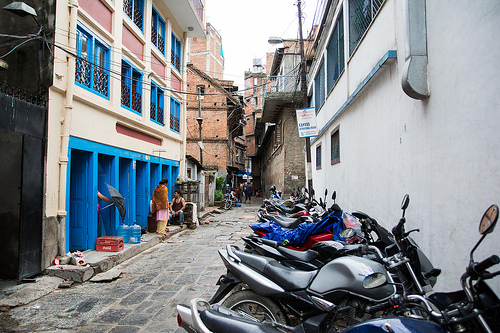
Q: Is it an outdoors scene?
A: Yes, it is outdoors.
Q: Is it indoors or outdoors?
A: It is outdoors.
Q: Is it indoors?
A: No, it is outdoors.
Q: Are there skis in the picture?
A: No, there are no skis.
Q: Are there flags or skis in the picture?
A: No, there are no skis or flags.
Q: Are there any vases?
A: No, there are no vases.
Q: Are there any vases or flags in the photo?
A: No, there are no vases or flags.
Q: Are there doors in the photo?
A: Yes, there is a door.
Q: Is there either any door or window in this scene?
A: Yes, there is a door.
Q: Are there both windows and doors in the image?
A: Yes, there are both a door and a window.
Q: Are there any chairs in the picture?
A: No, there are no chairs.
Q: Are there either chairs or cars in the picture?
A: No, there are no chairs or cars.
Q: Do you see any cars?
A: No, there are no cars.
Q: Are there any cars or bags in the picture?
A: No, there are no cars or bags.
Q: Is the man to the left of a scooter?
A: No, the man is to the left of a motorcycle.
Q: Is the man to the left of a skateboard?
A: No, the man is to the left of a motorcycle.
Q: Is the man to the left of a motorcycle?
A: Yes, the man is to the left of a motorcycle.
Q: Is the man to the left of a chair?
A: No, the man is to the left of a motorcycle.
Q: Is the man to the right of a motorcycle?
A: No, the man is to the left of a motorcycle.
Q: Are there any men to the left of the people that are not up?
A: Yes, there is a man to the left of the people.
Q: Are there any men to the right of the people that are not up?
A: No, the man is to the left of the people.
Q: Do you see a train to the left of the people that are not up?
A: No, there is a man to the left of the people.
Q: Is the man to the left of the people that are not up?
A: Yes, the man is to the left of the people.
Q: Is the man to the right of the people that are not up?
A: No, the man is to the left of the people.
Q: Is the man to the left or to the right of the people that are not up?
A: The man is to the left of the people.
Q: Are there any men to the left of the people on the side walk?
A: Yes, there is a man to the left of the people.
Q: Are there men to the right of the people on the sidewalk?
A: No, the man is to the left of the people.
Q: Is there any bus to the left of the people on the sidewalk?
A: No, there is a man to the left of the people.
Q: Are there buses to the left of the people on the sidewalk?
A: No, there is a man to the left of the people.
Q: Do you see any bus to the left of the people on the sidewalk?
A: No, there is a man to the left of the people.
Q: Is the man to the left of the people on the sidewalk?
A: Yes, the man is to the left of the people.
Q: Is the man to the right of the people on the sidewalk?
A: No, the man is to the left of the people.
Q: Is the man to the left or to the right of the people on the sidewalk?
A: The man is to the left of the people.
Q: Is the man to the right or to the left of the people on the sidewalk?
A: The man is to the left of the people.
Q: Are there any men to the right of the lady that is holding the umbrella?
A: Yes, there is a man to the right of the lady.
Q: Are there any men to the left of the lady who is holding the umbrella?
A: No, the man is to the right of the lady.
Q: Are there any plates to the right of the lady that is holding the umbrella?
A: No, there is a man to the right of the lady.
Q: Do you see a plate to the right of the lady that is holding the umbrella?
A: No, there is a man to the right of the lady.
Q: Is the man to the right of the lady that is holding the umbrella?
A: Yes, the man is to the right of the lady.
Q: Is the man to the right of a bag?
A: No, the man is to the right of the lady.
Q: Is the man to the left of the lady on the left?
A: No, the man is to the right of the lady.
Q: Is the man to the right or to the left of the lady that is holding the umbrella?
A: The man is to the right of the lady.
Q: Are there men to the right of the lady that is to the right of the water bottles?
A: Yes, there is a man to the right of the lady.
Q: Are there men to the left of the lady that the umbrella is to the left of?
A: No, the man is to the right of the lady.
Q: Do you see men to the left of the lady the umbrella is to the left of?
A: No, the man is to the right of the lady.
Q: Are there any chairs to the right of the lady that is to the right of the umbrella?
A: No, there is a man to the right of the lady.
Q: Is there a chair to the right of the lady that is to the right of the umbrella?
A: No, there is a man to the right of the lady.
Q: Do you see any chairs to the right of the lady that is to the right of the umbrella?
A: No, there is a man to the right of the lady.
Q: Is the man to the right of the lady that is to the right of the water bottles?
A: Yes, the man is to the right of the lady.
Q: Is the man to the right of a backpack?
A: No, the man is to the right of the lady.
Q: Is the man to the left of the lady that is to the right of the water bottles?
A: No, the man is to the right of the lady.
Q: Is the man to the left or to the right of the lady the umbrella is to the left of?
A: The man is to the right of the lady.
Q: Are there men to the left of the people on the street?
A: Yes, there is a man to the left of the people.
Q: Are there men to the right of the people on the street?
A: No, the man is to the left of the people.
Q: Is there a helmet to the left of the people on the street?
A: No, there is a man to the left of the people.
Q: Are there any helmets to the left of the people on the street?
A: No, there is a man to the left of the people.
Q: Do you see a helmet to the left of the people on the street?
A: No, there is a man to the left of the people.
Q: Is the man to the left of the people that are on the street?
A: Yes, the man is to the left of the people.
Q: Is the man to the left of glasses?
A: No, the man is to the left of the people.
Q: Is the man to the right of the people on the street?
A: No, the man is to the left of the people.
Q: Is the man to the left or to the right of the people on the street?
A: The man is to the left of the people.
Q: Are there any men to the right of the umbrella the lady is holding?
A: Yes, there is a man to the right of the umbrella.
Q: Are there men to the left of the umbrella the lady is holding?
A: No, the man is to the right of the umbrella.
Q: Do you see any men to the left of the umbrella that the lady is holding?
A: No, the man is to the right of the umbrella.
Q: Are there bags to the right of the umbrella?
A: No, there is a man to the right of the umbrella.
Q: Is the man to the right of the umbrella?
A: Yes, the man is to the right of the umbrella.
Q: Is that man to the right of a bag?
A: No, the man is to the right of the umbrella.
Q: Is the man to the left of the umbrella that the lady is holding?
A: No, the man is to the right of the umbrella.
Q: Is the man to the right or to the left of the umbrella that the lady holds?
A: The man is to the right of the umbrella.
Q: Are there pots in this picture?
A: No, there are no pots.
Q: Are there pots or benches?
A: No, there are no pots or benches.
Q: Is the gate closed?
A: Yes, the gate is closed.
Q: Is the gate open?
A: No, the gate is closed.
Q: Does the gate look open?
A: No, the gate is closed.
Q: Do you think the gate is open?
A: No, the gate is closed.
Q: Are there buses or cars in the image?
A: No, there are no cars or buses.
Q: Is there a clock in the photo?
A: No, there are no clocks.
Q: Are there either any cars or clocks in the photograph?
A: No, there are no clocks or cars.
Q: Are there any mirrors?
A: Yes, there is a mirror.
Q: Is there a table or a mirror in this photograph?
A: Yes, there is a mirror.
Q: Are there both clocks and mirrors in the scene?
A: No, there is a mirror but no clocks.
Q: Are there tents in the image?
A: No, there are no tents.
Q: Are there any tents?
A: No, there are no tents.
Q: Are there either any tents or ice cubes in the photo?
A: No, there are no tents or ice cubes.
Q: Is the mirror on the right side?
A: Yes, the mirror is on the right of the image.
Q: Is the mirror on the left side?
A: No, the mirror is on the right of the image.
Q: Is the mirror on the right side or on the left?
A: The mirror is on the right of the image.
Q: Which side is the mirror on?
A: The mirror is on the right of the image.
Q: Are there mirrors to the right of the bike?
A: Yes, there is a mirror to the right of the bike.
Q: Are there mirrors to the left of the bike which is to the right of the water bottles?
A: No, the mirror is to the right of the bike.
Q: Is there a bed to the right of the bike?
A: No, there is a mirror to the right of the bike.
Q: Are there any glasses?
A: No, there are no glasses.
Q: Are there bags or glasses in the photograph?
A: No, there are no glasses or bags.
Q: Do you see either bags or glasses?
A: No, there are no glasses or bags.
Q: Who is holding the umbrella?
A: The lady is holding the umbrella.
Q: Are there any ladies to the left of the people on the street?
A: Yes, there is a lady to the left of the people.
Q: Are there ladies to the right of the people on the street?
A: No, the lady is to the left of the people.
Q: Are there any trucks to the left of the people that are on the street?
A: No, there is a lady to the left of the people.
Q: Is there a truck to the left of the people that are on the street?
A: No, there is a lady to the left of the people.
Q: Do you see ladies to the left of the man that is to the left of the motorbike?
A: Yes, there is a lady to the left of the man.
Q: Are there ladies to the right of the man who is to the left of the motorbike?
A: No, the lady is to the left of the man.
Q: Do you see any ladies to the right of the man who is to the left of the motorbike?
A: No, the lady is to the left of the man.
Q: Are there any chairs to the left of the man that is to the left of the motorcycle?
A: No, there is a lady to the left of the man.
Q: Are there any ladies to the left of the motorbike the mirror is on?
A: Yes, there is a lady to the left of the motorcycle.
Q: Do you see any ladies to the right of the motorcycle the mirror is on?
A: No, the lady is to the left of the motorcycle.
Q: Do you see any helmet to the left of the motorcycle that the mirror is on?
A: No, there is a lady to the left of the motorbike.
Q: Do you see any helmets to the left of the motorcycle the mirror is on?
A: No, there is a lady to the left of the motorbike.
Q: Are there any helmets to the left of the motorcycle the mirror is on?
A: No, there is a lady to the left of the motorbike.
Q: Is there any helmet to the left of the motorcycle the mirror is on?
A: No, there is a lady to the left of the motorbike.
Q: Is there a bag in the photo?
A: No, there are no bags.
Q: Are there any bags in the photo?
A: No, there are no bags.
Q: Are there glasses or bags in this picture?
A: No, there are no bags or glasses.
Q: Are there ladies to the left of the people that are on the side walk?
A: Yes, there is a lady to the left of the people.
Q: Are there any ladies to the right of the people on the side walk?
A: No, the lady is to the left of the people.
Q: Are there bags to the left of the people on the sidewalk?
A: No, there is a lady to the left of the people.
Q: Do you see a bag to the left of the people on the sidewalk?
A: No, there is a lady to the left of the people.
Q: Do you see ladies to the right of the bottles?
A: Yes, there is a lady to the right of the bottles.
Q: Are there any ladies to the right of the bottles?
A: Yes, there is a lady to the right of the bottles.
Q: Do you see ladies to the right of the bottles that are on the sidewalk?
A: Yes, there is a lady to the right of the bottles.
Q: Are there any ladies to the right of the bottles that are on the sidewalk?
A: Yes, there is a lady to the right of the bottles.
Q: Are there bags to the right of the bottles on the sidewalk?
A: No, there is a lady to the right of the bottles.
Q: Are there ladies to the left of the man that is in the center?
A: Yes, there is a lady to the left of the man.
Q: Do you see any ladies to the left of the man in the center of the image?
A: Yes, there is a lady to the left of the man.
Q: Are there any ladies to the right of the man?
A: No, the lady is to the left of the man.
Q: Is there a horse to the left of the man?
A: No, there is a lady to the left of the man.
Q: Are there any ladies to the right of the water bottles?
A: Yes, there is a lady to the right of the water bottles.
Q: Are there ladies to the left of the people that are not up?
A: Yes, there is a lady to the left of the people.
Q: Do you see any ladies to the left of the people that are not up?
A: Yes, there is a lady to the left of the people.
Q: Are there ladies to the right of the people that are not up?
A: No, the lady is to the left of the people.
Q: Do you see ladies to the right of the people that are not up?
A: No, the lady is to the left of the people.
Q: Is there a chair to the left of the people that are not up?
A: No, there is a lady to the left of the people.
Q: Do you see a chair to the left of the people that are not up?
A: No, there is a lady to the left of the people.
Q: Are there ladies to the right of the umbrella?
A: Yes, there is a lady to the right of the umbrella.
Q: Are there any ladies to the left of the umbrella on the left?
A: No, the lady is to the right of the umbrella.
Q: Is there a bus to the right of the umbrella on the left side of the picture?
A: No, there is a lady to the right of the umbrella.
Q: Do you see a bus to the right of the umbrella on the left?
A: No, there is a lady to the right of the umbrella.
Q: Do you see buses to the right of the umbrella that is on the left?
A: No, there is a lady to the right of the umbrella.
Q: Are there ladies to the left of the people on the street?
A: Yes, there is a lady to the left of the people.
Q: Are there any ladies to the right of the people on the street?
A: No, the lady is to the left of the people.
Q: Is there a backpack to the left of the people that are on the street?
A: No, there is a lady to the left of the people.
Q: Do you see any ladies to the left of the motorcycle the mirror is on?
A: Yes, there is a lady to the left of the motorcycle.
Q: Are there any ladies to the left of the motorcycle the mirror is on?
A: Yes, there is a lady to the left of the motorcycle.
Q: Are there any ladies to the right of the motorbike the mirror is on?
A: No, the lady is to the left of the motorbike.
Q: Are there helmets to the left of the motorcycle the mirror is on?
A: No, there is a lady to the left of the motorbike.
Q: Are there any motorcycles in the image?
A: Yes, there is a motorcycle.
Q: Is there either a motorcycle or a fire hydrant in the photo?
A: Yes, there is a motorcycle.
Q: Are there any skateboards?
A: No, there are no skateboards.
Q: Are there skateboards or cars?
A: No, there are no skateboards or cars.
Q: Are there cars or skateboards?
A: No, there are no skateboards or cars.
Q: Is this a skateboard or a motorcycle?
A: This is a motorcycle.